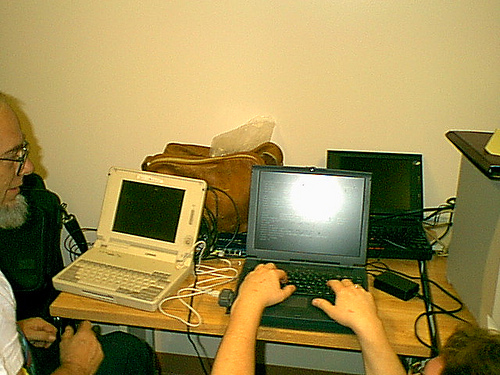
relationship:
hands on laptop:
[209, 261, 406, 373] [237, 162, 370, 334]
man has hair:
[0, 91, 160, 375] [2, 199, 26, 227]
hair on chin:
[2, 199, 26, 227] [1, 196, 23, 216]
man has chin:
[0, 91, 160, 375] [1, 196, 23, 216]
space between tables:
[417, 253, 445, 353] [42, 213, 499, 360]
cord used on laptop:
[371, 268, 419, 300] [237, 162, 370, 334]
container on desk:
[453, 127, 495, 322] [384, 298, 460, 336]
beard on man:
[1, 193, 33, 232] [0, 94, 37, 234]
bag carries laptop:
[0, 187, 88, 322] [237, 162, 370, 334]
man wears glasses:
[0, 95, 160, 374] [1, 139, 26, 172]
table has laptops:
[49, 182, 496, 358] [51, 147, 432, 330]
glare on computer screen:
[290, 175, 343, 224] [246, 164, 372, 265]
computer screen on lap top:
[248, 157, 379, 262] [226, 149, 397, 343]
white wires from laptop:
[170, 242, 234, 317] [237, 162, 370, 334]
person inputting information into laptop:
[212, 263, 497, 372] [237, 162, 370, 334]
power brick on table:
[370, 268, 419, 303] [396, 309, 438, 358]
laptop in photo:
[75, 163, 221, 325] [65, 203, 435, 346]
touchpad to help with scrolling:
[280, 292, 310, 311] [382, 264, 431, 323]